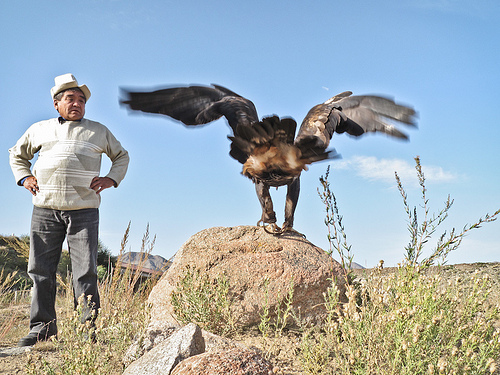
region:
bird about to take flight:
[113, 77, 416, 234]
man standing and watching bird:
[6, 70, 130, 349]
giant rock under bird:
[143, 222, 358, 345]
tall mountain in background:
[118, 249, 175, 277]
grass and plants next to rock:
[302, 152, 499, 372]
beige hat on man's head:
[47, 72, 92, 99]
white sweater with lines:
[8, 116, 130, 211]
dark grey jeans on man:
[25, 205, 105, 335]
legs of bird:
[253, 177, 304, 234]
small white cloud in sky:
[332, 153, 454, 188]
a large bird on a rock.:
[115, 58, 418, 255]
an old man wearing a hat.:
[43, 69, 106, 135]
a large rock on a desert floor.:
[90, 203, 381, 370]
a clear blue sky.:
[0, 0, 496, 268]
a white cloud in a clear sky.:
[313, 153, 466, 195]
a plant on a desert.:
[290, 153, 495, 290]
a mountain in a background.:
[103, 253, 176, 276]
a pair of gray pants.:
[19, 203, 109, 334]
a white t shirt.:
[0, 122, 139, 219]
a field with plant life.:
[0, 240, 498, 370]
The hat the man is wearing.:
[49, 70, 94, 100]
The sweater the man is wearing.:
[15, 110, 118, 202]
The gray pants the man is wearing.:
[24, 208, 105, 328]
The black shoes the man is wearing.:
[17, 330, 100, 350]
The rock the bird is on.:
[167, 219, 352, 350]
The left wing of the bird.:
[120, 83, 261, 140]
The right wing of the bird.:
[298, 88, 413, 148]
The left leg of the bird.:
[251, 176, 273, 233]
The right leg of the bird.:
[282, 176, 302, 224]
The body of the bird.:
[240, 129, 307, 179]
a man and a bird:
[28, 52, 403, 352]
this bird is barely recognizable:
[128, 44, 429, 270]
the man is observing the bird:
[10, 62, 322, 347]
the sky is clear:
[13, 17, 460, 263]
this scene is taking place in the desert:
[5, 197, 497, 362]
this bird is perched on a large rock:
[131, 49, 409, 358]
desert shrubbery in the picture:
[318, 170, 495, 354]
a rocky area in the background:
[118, 239, 208, 301]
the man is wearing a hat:
[35, 57, 107, 124]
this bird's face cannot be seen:
[228, 112, 325, 204]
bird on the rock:
[193, 32, 424, 210]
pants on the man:
[7, 235, 132, 307]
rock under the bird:
[180, 235, 320, 310]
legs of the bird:
[230, 190, 307, 232]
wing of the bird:
[315, 80, 395, 161]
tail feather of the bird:
[253, 109, 298, 156]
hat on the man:
[43, 73, 95, 98]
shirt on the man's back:
[21, 116, 127, 191]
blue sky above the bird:
[348, 19, 402, 46]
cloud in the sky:
[361, 157, 400, 191]